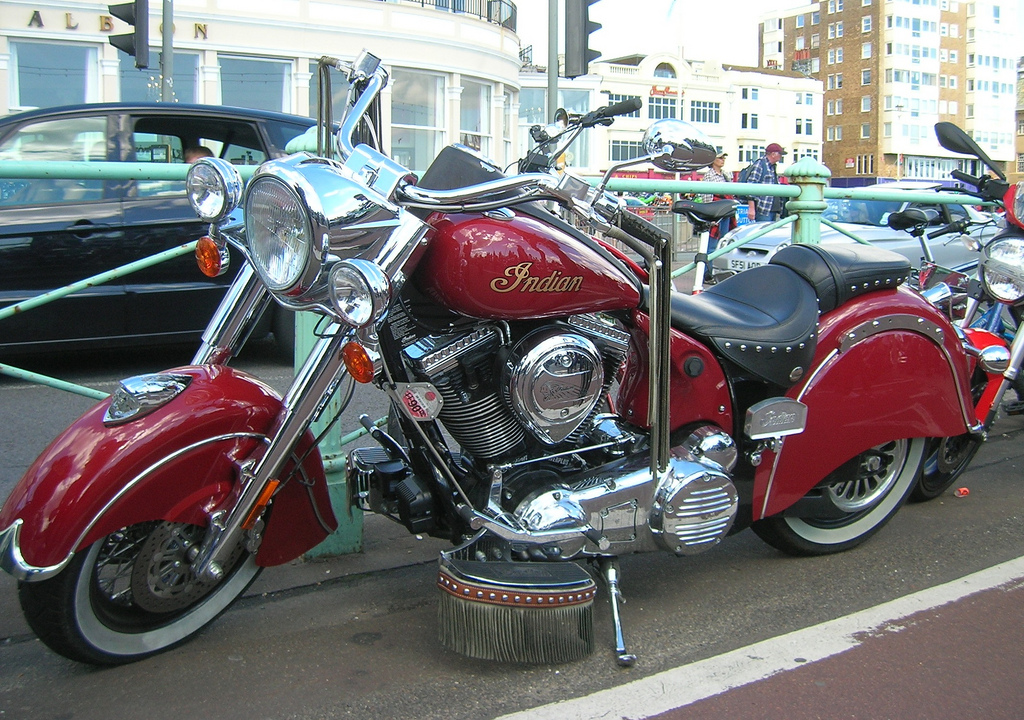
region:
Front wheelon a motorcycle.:
[25, 363, 310, 677]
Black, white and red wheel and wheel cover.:
[13, 355, 314, 682]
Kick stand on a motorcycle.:
[563, 534, 666, 690]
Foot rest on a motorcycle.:
[432, 530, 606, 673]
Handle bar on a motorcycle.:
[303, 34, 637, 266]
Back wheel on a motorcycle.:
[774, 320, 937, 554]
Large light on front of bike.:
[236, 183, 316, 285]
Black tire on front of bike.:
[15, 489, 292, 673]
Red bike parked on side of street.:
[76, 184, 944, 584]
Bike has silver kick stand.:
[584, 544, 651, 675]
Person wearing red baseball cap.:
[764, 138, 790, 165]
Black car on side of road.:
[27, 108, 303, 333]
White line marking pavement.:
[565, 579, 999, 717]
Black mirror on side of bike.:
[929, 108, 1002, 192]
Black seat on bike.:
[691, 252, 821, 379]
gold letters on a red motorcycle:
[496, 253, 598, 307]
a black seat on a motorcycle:
[656, 257, 819, 372]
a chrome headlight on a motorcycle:
[238, 175, 378, 293]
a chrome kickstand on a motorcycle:
[596, 556, 648, 674]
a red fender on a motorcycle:
[17, 361, 312, 564]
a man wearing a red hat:
[759, 139, 789, 163]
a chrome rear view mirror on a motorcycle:
[637, 117, 723, 175]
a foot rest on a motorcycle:
[438, 558, 600, 664]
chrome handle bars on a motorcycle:
[332, 54, 639, 247]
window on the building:
[130, 41, 204, 103]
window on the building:
[229, 50, 293, 108]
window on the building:
[330, 81, 351, 114]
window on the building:
[383, 75, 428, 132]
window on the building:
[656, 102, 680, 118]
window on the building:
[675, 104, 721, 131]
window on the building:
[788, 105, 811, 141]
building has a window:
[385, 68, 458, 126]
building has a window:
[210, 52, 297, 111]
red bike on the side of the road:
[3, 50, 1015, 692]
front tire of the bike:
[9, 464, 279, 677]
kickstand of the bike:
[597, 546, 640, 680]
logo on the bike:
[484, 253, 592, 308]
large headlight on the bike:
[240, 174, 317, 301]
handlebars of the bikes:
[310, 45, 684, 262]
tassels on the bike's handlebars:
[638, 252, 676, 490]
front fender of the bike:
[12, 363, 345, 583]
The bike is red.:
[1, 95, 1011, 677]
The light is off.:
[231, 176, 324, 295]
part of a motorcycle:
[435, 563, 597, 672]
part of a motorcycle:
[582, 552, 643, 676]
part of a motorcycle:
[18, 353, 339, 676]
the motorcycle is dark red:
[2, 53, 1021, 667]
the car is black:
[1, 101, 357, 374]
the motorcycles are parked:
[2, 53, 1020, 668]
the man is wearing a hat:
[737, 142, 789, 228]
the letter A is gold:
[24, 6, 44, 29]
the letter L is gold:
[61, 6, 80, 36]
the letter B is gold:
[95, 10, 115, 34]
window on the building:
[880, 89, 903, 112]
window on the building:
[792, 113, 824, 148]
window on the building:
[798, 139, 830, 171]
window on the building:
[719, 162, 771, 170]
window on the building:
[629, 86, 669, 124]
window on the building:
[579, 118, 669, 191]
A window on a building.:
[857, 119, 873, 140]